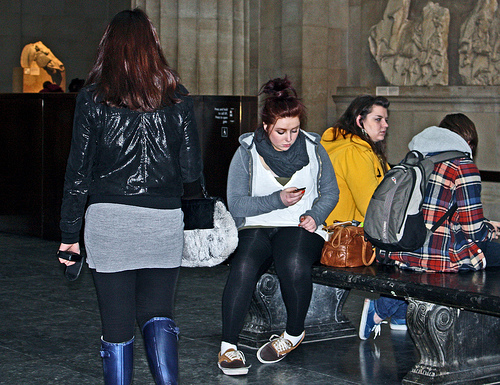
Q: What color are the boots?
A: Blue.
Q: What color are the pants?
A: Black.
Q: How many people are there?
A: Four.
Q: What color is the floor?
A: Gray.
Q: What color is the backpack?
A: Gray.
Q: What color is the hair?
A: Brown.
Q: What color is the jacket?
A: Yellow.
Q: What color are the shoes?
A: Black.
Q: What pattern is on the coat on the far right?
A: Plain.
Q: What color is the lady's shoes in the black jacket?
A: Blue.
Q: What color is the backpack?
A: Grey.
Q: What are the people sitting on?
A: Bench.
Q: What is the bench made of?
A: Concrete.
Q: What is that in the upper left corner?
A: Statue.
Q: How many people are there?
A: Four.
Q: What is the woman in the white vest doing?
A: Looking at her phone.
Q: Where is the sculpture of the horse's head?
A: To the left.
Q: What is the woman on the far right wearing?
A: A plaid jacket.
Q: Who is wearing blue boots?
A: The woman standing up.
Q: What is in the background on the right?
A: Stone artwork.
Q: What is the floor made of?
A: Marble.